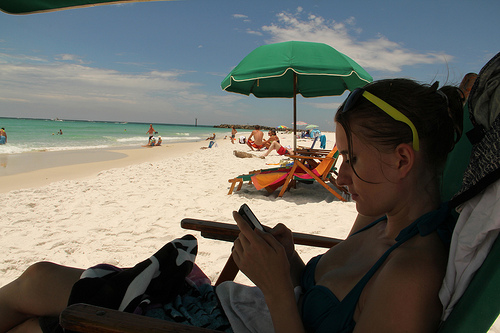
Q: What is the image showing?
A: It is showing a beach.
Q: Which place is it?
A: It is a beach.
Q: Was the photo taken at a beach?
A: Yes, it was taken in a beach.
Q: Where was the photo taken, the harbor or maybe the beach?
A: It was taken at the beach.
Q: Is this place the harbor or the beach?
A: It is the beach.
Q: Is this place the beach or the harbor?
A: It is the beach.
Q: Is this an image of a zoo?
A: No, the picture is showing a beach.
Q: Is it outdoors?
A: Yes, it is outdoors.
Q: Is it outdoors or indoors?
A: It is outdoors.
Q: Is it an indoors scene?
A: No, it is outdoors.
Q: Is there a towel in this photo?
A: Yes, there is a towel.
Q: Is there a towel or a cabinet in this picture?
A: Yes, there is a towel.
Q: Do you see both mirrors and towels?
A: No, there is a towel but no mirrors.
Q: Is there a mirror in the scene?
A: No, there are no mirrors.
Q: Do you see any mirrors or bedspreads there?
A: No, there are no mirrors or bedspreads.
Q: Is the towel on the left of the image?
A: Yes, the towel is on the left of the image.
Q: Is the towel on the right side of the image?
A: No, the towel is on the left of the image.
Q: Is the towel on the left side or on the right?
A: The towel is on the left of the image.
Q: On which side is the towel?
A: The towel is on the left of the image.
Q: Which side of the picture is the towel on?
A: The towel is on the left of the image.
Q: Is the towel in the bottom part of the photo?
A: Yes, the towel is in the bottom of the image.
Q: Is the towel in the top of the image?
A: No, the towel is in the bottom of the image.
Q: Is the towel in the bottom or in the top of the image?
A: The towel is in the bottom of the image.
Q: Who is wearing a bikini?
A: The girl is wearing a bikini.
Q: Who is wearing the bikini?
A: The girl is wearing a bikini.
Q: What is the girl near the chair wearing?
A: The girl is wearing a bikini.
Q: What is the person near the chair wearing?
A: The girl is wearing a bikini.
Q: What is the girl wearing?
A: The girl is wearing a bikini.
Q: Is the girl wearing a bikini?
A: Yes, the girl is wearing a bikini.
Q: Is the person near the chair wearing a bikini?
A: Yes, the girl is wearing a bikini.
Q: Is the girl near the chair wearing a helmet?
A: No, the girl is wearing a bikini.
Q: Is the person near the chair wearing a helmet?
A: No, the girl is wearing a bikini.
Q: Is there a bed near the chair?
A: No, there is a girl near the chair.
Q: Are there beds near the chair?
A: No, there is a girl near the chair.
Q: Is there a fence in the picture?
A: No, there are no fences.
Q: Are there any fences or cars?
A: No, there are no fences or cars.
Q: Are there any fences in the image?
A: No, there are no fences.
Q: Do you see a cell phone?
A: Yes, there is a cell phone.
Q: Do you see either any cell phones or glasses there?
A: Yes, there is a cell phone.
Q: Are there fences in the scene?
A: No, there are no fences.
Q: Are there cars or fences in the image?
A: No, there are no fences or cars.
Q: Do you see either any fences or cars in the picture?
A: No, there are no fences or cars.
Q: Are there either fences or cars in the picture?
A: No, there are no fences or cars.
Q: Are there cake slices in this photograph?
A: No, there are no cake slices.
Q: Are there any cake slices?
A: No, there are no cake slices.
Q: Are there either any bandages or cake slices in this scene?
A: No, there are no cake slices or bandages.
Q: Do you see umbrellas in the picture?
A: Yes, there is an umbrella.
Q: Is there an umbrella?
A: Yes, there is an umbrella.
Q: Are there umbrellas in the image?
A: Yes, there is an umbrella.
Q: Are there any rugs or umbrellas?
A: Yes, there is an umbrella.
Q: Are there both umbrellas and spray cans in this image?
A: No, there is an umbrella but no spray cans.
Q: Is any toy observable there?
A: No, there are no toys.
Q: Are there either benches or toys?
A: No, there are no toys or benches.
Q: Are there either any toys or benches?
A: No, there are no toys or benches.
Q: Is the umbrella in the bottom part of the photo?
A: No, the umbrella is in the top of the image.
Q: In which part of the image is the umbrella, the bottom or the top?
A: The umbrella is in the top of the image.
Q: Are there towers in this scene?
A: No, there are no towers.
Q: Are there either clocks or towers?
A: No, there are no towers or clocks.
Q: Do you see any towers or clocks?
A: No, there are no towers or clocks.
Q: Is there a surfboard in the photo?
A: No, there are no surfboards.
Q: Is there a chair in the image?
A: Yes, there is a chair.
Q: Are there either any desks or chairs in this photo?
A: Yes, there is a chair.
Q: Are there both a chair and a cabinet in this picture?
A: No, there is a chair but no cabinets.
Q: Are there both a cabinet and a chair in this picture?
A: No, there is a chair but no cabinets.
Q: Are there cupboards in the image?
A: No, there are no cupboards.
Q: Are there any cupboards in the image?
A: No, there are no cupboards.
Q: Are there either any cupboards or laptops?
A: No, there are no cupboards or laptops.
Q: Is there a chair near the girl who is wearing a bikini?
A: Yes, there is a chair near the girl.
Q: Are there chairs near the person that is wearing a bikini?
A: Yes, there is a chair near the girl.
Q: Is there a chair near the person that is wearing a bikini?
A: Yes, there is a chair near the girl.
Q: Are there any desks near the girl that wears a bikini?
A: No, there is a chair near the girl.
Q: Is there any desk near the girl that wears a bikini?
A: No, there is a chair near the girl.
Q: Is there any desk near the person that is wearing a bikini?
A: No, there is a chair near the girl.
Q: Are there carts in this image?
A: No, there are no carts.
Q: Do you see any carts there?
A: No, there are no carts.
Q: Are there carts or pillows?
A: No, there are no carts or pillows.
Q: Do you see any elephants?
A: No, there are no elephants.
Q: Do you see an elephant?
A: No, there are no elephants.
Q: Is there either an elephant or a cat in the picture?
A: No, there are no elephants or cats.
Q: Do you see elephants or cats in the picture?
A: No, there are no elephants or cats.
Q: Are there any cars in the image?
A: No, there are no cars.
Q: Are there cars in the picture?
A: No, there are no cars.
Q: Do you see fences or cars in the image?
A: No, there are no cars or fences.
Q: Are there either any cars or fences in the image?
A: No, there are no cars or fences.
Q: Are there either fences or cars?
A: No, there are no cars or fences.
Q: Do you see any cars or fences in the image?
A: No, there are no cars or fences.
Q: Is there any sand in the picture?
A: Yes, there is sand.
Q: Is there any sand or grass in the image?
A: Yes, there is sand.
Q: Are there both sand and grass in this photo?
A: No, there is sand but no grass.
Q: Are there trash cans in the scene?
A: No, there are no trash cans.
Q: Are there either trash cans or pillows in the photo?
A: No, there are no trash cans or pillows.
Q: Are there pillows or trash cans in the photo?
A: No, there are no trash cans or pillows.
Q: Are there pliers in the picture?
A: No, there are no pliers.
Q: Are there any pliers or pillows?
A: No, there are no pliers or pillows.